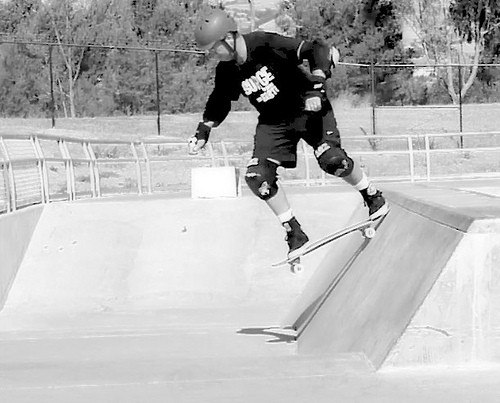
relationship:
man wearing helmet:
[182, 16, 382, 239] [186, 13, 238, 45]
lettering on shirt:
[242, 75, 274, 105] [210, 61, 314, 121]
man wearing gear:
[182, 16, 382, 239] [243, 156, 280, 209]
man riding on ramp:
[182, 16, 382, 239] [209, 222, 483, 365]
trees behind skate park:
[21, 7, 232, 97] [16, 9, 499, 269]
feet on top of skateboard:
[354, 198, 397, 218] [282, 224, 384, 263]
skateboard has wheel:
[282, 224, 384, 263] [291, 259, 310, 277]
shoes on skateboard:
[283, 223, 312, 248] [282, 224, 384, 263]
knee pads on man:
[242, 158, 281, 206] [182, 16, 382, 239]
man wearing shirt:
[182, 16, 382, 239] [210, 61, 314, 121]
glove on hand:
[191, 120, 212, 142] [184, 121, 213, 157]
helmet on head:
[186, 13, 238, 45] [196, 25, 257, 71]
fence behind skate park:
[32, 45, 498, 150] [16, 9, 499, 269]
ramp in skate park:
[209, 222, 483, 365] [16, 9, 499, 269]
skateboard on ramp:
[282, 224, 384, 263] [209, 222, 483, 365]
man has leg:
[182, 16, 382, 239] [245, 163, 304, 254]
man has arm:
[182, 16, 382, 239] [293, 36, 334, 117]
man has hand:
[182, 16, 382, 239] [184, 121, 213, 157]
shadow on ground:
[72, 240, 232, 323] [24, 265, 426, 401]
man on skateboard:
[182, 16, 382, 239] [282, 224, 384, 263]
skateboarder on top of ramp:
[193, 17, 356, 234] [209, 222, 483, 365]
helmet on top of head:
[186, 13, 238, 45] [196, 25, 257, 71]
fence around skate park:
[32, 45, 498, 150] [16, 9, 499, 269]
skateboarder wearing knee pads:
[193, 17, 356, 234] [242, 158, 281, 206]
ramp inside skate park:
[209, 222, 483, 365] [16, 9, 499, 269]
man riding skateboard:
[182, 16, 382, 239] [282, 224, 384, 263]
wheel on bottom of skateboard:
[291, 259, 310, 277] [282, 224, 384, 263]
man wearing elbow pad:
[182, 16, 382, 239] [303, 41, 336, 70]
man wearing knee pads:
[182, 16, 382, 239] [242, 158, 281, 206]